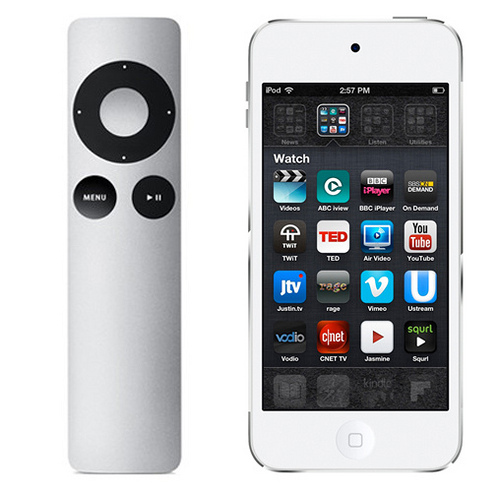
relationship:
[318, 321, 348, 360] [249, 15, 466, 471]
button on ipod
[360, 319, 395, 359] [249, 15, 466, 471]
button on ipod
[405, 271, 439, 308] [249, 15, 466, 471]
button on ipod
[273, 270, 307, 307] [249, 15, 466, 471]
button on ipod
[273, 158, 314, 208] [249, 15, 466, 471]
button on ipod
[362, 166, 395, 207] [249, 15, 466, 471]
button on ipod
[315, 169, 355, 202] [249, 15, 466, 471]
button on ipod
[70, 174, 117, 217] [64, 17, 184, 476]
menu button on remote control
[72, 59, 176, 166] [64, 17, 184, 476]
directional button on remote control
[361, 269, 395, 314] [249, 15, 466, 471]
vimeo button on ipod